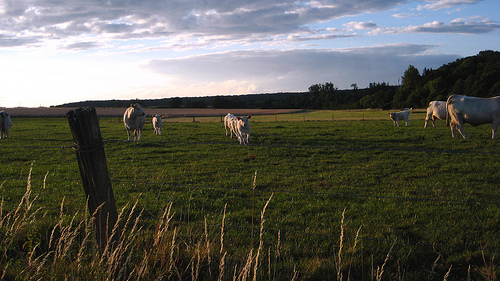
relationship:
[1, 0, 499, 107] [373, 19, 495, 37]
sky with cloud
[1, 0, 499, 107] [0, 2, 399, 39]
sky with cloud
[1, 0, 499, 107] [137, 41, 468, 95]
sky with clouds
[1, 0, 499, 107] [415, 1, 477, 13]
sky with cloud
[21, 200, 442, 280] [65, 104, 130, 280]
yellow weeds near a fence post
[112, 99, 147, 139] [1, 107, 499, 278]
cow in a pasture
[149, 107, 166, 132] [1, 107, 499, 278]
cow in a pasture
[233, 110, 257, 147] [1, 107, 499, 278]
cow in a pasture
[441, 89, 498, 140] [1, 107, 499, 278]
cow in a pasture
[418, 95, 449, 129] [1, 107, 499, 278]
cow in a pasture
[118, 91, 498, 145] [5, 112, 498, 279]
cattle herd walking in grass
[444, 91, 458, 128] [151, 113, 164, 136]
tail of cow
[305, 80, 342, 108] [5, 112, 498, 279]
tree behind grass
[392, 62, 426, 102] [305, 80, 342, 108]
tree behind tree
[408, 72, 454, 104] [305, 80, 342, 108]
tree behind tree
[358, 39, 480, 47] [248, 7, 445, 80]
sky behind cloud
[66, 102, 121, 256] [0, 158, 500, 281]
fence post with yellow weeds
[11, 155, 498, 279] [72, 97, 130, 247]
plants next to fence post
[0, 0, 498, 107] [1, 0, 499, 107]
clouds in sky